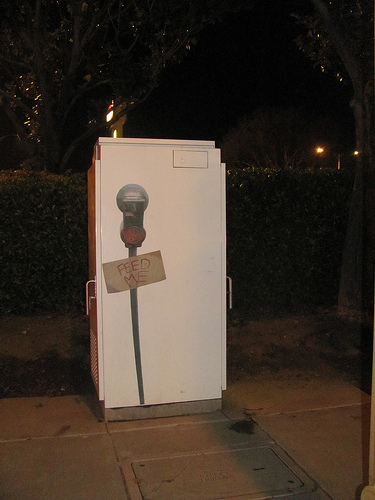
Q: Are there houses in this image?
A: No, there are no houses.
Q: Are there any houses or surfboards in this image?
A: No, there are no houses or surfboards.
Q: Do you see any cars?
A: No, there are no cars.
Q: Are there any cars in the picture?
A: No, there are no cars.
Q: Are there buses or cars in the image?
A: No, there are no cars or buses.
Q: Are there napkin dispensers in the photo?
A: No, there are no napkin dispensers.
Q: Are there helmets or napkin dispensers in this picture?
A: No, there are no napkin dispensers or helmets.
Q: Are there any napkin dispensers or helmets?
A: No, there are no napkin dispensers or helmets.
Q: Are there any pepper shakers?
A: No, there are no pepper shakers.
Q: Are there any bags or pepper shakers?
A: No, there are no pepper shakers or bags.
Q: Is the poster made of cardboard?
A: Yes, the poster is made of cardboard.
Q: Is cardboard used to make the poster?
A: Yes, the poster is made of cardboard.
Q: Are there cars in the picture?
A: No, there are no cars.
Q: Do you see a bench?
A: No, there are no benches.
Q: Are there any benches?
A: No, there are no benches.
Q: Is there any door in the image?
A: Yes, there is a door.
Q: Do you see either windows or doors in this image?
A: Yes, there is a door.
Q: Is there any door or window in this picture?
A: Yes, there is a door.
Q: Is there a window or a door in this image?
A: Yes, there is a door.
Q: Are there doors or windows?
A: Yes, there is a door.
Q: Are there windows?
A: No, there are no windows.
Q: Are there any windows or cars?
A: No, there are no windows or cars.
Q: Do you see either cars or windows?
A: No, there are no windows or cars.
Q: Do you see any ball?
A: No, there are no balls.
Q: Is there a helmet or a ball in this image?
A: No, there are no balls or helmets.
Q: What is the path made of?
A: The path is made of concrete.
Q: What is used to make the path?
A: The path is made of concrete.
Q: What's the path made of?
A: The path is made of concrete.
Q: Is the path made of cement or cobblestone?
A: The path is made of cement.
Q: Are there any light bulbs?
A: No, there are no light bulbs.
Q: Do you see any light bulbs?
A: No, there are no light bulbs.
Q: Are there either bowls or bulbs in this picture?
A: No, there are no bulbs or bowls.